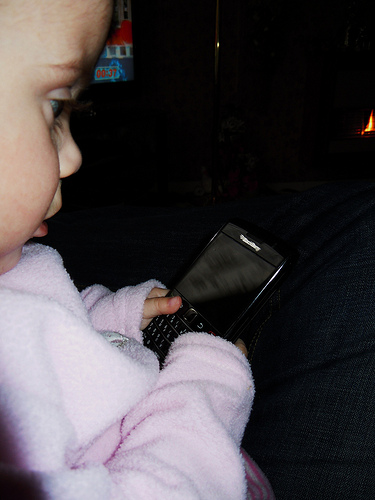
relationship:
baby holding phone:
[5, 2, 256, 498] [136, 221, 284, 362]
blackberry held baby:
[128, 224, 284, 369] [0, 2, 256, 498]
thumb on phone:
[140, 293, 182, 316] [148, 227, 285, 360]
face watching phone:
[5, 0, 112, 250] [136, 221, 284, 362]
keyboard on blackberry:
[141, 310, 188, 354] [127, 218, 289, 358]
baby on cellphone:
[0, 2, 256, 498] [137, 217, 297, 359]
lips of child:
[38, 202, 60, 247] [2, 7, 241, 444]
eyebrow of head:
[47, 54, 95, 76] [0, 11, 106, 277]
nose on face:
[49, 114, 87, 184] [0, 4, 118, 286]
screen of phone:
[183, 230, 259, 315] [155, 220, 278, 363]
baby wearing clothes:
[5, 2, 256, 498] [1, 248, 253, 498]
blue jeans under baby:
[291, 444, 356, 494] [5, 8, 294, 492]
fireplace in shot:
[350, 101, 362, 133] [6, 9, 352, 493]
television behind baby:
[76, 26, 144, 90] [0, 2, 256, 498]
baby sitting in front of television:
[0, 2, 256, 498] [76, 26, 144, 90]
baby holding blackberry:
[5, 2, 256, 498] [128, 224, 284, 369]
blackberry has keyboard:
[128, 224, 284, 369] [141, 310, 188, 354]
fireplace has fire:
[352, 101, 362, 129] [357, 117, 362, 125]